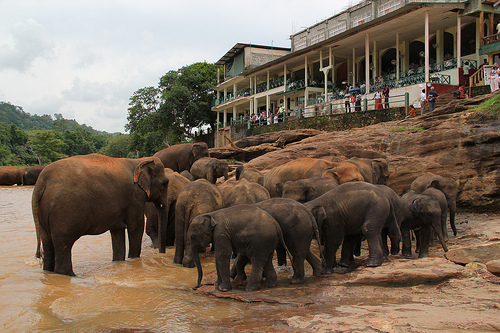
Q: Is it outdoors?
A: Yes, it is outdoors.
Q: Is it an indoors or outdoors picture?
A: It is outdoors.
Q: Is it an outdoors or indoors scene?
A: It is outdoors.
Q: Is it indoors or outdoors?
A: It is outdoors.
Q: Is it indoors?
A: No, it is outdoors.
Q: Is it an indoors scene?
A: No, it is outdoors.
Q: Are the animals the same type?
A: Yes, all the animals are elephants.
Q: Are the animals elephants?
A: Yes, all the animals are elephants.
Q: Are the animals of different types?
A: No, all the animals are elephants.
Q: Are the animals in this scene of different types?
A: No, all the animals are elephants.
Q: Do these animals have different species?
A: No, all the animals are elephants.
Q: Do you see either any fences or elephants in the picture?
A: Yes, there is an elephant.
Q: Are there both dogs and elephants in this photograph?
A: No, there is an elephant but no dogs.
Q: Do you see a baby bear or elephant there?
A: Yes, there is a baby elephant.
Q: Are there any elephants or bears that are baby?
A: Yes, the elephant is a baby.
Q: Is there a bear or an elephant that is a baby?
A: Yes, the elephant is a baby.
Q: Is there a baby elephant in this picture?
A: Yes, there is a baby elephant.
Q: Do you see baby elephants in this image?
A: Yes, there is a baby elephant.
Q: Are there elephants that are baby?
A: Yes, there is an elephant that is a baby.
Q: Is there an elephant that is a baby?
A: Yes, there is an elephant that is a baby.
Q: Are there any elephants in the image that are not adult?
A: Yes, there is an baby elephant.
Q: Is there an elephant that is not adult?
A: Yes, there is an baby elephant.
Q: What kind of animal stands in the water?
A: The animal is an elephant.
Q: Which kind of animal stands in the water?
A: The animal is an elephant.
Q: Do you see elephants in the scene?
A: Yes, there is an elephant.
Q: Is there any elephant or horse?
A: Yes, there is an elephant.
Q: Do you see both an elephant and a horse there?
A: No, there is an elephant but no horses.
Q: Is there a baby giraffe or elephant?
A: Yes, there is a baby elephant.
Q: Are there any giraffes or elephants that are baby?
A: Yes, the elephant is a baby.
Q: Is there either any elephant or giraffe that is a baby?
A: Yes, the elephant is a baby.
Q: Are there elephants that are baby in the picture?
A: Yes, there is a baby elephant.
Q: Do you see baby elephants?
A: Yes, there is a baby elephant.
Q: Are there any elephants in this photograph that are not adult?
A: Yes, there is an baby elephant.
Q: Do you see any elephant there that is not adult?
A: Yes, there is an baby elephant.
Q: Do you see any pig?
A: No, there are no pigs.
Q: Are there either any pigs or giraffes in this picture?
A: No, there are no pigs or giraffes.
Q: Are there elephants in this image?
A: Yes, there is an elephant.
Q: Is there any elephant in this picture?
A: Yes, there is an elephant.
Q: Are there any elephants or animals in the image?
A: Yes, there is an elephant.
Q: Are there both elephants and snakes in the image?
A: No, there is an elephant but no snakes.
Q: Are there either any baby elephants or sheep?
A: Yes, there is a baby elephant.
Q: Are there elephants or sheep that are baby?
A: Yes, the elephant is a baby.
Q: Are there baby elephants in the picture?
A: Yes, there is a baby elephant.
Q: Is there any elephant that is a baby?
A: Yes, there is an elephant that is a baby.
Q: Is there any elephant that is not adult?
A: Yes, there is an baby elephant.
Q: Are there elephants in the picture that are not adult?
A: Yes, there is an baby elephant.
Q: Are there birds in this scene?
A: No, there are no birds.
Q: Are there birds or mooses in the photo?
A: No, there are no birds or mooses.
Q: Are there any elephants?
A: Yes, there is an elephant.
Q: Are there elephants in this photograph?
A: Yes, there is an elephant.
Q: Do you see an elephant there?
A: Yes, there is an elephant.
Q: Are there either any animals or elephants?
A: Yes, there is an elephant.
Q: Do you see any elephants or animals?
A: Yes, there is an elephant.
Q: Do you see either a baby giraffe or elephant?
A: Yes, there is a baby elephant.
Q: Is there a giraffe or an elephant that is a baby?
A: Yes, the elephant is a baby.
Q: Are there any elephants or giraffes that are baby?
A: Yes, the elephant is a baby.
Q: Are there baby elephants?
A: Yes, there is a baby elephant.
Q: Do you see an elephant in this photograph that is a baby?
A: Yes, there is an elephant that is a baby.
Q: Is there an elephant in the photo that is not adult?
A: Yes, there is an baby elephant.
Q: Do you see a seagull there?
A: No, there are no seagulls.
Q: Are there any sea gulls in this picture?
A: No, there are no sea gulls.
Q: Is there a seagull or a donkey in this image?
A: No, there are no seagulls or donkeys.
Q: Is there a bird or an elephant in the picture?
A: Yes, there is an elephant.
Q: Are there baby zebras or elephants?
A: Yes, there is a baby elephant.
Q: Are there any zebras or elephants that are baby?
A: Yes, the elephant is a baby.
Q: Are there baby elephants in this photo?
A: Yes, there is a baby elephant.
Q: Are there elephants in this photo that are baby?
A: Yes, there is an elephant that is a baby.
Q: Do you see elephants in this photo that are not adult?
A: Yes, there is an baby elephant.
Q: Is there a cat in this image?
A: No, there are no cats.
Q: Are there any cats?
A: No, there are no cats.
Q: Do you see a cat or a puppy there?
A: No, there are no cats or puppys.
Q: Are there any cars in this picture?
A: No, there are no cars.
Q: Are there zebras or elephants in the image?
A: Yes, there is an elephant.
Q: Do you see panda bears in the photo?
A: No, there are no panda bears.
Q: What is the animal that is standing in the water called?
A: The animal is an elephant.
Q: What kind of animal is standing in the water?
A: The animal is an elephant.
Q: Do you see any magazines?
A: No, there are no magazines.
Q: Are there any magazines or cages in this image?
A: No, there are no magazines or cages.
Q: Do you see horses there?
A: No, there are no horses.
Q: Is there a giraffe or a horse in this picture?
A: No, there are no horses or giraffes.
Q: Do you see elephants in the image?
A: Yes, there is an elephant.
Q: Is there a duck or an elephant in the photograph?
A: Yes, there is an elephant.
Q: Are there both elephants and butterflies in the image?
A: No, there is an elephant but no butterflies.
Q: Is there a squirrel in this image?
A: No, there are no squirrels.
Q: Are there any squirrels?
A: No, there are no squirrels.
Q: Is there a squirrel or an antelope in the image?
A: No, there are no squirrels or antelopes.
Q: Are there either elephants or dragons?
A: Yes, there is an elephant.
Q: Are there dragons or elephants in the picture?
A: Yes, there is an elephant.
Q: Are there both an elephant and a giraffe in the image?
A: No, there is an elephant but no giraffes.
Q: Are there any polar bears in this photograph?
A: No, there are no polar bears.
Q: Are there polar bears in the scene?
A: No, there are no polar bears.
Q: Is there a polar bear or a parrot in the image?
A: No, there are no polar bears or parrots.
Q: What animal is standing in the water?
A: The elephant is standing in the water.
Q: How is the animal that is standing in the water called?
A: The animal is an elephant.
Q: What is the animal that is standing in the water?
A: The animal is an elephant.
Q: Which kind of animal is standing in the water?
A: The animal is an elephant.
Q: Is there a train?
A: No, there are no trains.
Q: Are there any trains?
A: No, there are no trains.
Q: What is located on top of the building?
A: The roof is on top of the building.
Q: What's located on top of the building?
A: The roof is on top of the building.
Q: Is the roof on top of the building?
A: Yes, the roof is on top of the building.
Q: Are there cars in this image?
A: No, there are no cars.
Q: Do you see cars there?
A: No, there are no cars.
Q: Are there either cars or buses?
A: No, there are no cars or buses.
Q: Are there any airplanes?
A: No, there are no airplanes.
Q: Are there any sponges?
A: No, there are no sponges.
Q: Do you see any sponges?
A: No, there are no sponges.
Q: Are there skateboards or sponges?
A: No, there are no sponges or skateboards.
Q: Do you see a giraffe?
A: No, there are no giraffes.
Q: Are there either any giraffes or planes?
A: No, there are no giraffes or planes.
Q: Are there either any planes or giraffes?
A: No, there are no giraffes or planes.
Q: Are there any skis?
A: No, there are no skis.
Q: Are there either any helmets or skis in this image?
A: No, there are no skis or helmets.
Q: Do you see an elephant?
A: Yes, there is an elephant.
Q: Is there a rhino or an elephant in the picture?
A: Yes, there is an elephant.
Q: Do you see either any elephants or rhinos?
A: Yes, there is an elephant.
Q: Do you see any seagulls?
A: No, there are no seagulls.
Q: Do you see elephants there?
A: Yes, there is an elephant.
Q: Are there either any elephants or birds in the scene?
A: Yes, there is an elephant.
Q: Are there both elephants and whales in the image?
A: No, there is an elephant but no whales.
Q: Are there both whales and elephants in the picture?
A: No, there is an elephant but no whales.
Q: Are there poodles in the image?
A: No, there are no poodles.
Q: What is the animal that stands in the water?
A: The animal is an elephant.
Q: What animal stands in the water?
A: The animal is an elephant.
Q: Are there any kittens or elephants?
A: Yes, there is an elephant.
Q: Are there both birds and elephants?
A: No, there is an elephant but no birds.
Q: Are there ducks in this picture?
A: No, there are no ducks.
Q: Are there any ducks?
A: No, there are no ducks.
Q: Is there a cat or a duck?
A: No, there are no ducks or cats.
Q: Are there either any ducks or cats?
A: No, there are no ducks or cats.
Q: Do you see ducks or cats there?
A: No, there are no ducks or cats.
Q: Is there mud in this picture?
A: Yes, there is mud.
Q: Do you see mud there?
A: Yes, there is mud.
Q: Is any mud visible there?
A: Yes, there is mud.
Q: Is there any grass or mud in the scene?
A: Yes, there is mud.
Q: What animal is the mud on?
A: The mud is on the elephant.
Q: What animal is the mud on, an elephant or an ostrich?
A: The mud is on an elephant.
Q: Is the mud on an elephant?
A: Yes, the mud is on an elephant.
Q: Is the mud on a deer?
A: No, the mud is on an elephant.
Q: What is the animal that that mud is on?
A: The animal is an elephant.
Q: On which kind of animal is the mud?
A: The mud is on the elephant.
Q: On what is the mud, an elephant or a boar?
A: The mud is on an elephant.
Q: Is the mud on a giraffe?
A: No, the mud is on an elephant.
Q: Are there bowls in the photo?
A: No, there are no bowls.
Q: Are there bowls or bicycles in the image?
A: No, there are no bowls or bicycles.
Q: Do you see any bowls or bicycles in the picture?
A: No, there are no bowls or bicycles.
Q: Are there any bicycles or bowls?
A: No, there are no bowls or bicycles.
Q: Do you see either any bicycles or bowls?
A: No, there are no bowls or bicycles.